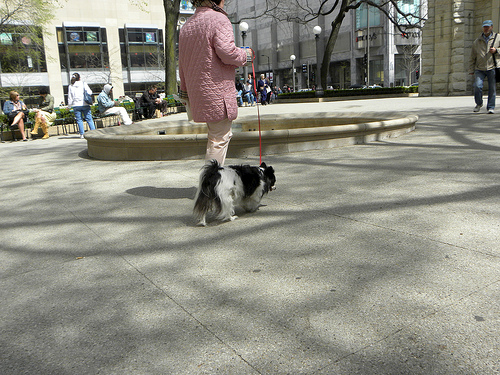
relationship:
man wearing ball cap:
[468, 20, 498, 115] [481, 17, 493, 27]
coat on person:
[175, 0, 250, 122] [178, 0, 254, 166]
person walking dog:
[178, 0, 254, 166] [196, 159, 274, 230]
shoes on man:
[467, 93, 498, 121] [469, 17, 485, 112]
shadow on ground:
[325, 106, 498, 189] [0, 95, 499, 374]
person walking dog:
[178, 0, 254, 166] [182, 154, 302, 239]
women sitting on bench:
[2, 83, 60, 142] [2, 110, 52, 142]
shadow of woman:
[127, 184, 196, 199] [177, 2, 252, 169]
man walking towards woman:
[468, 20, 500, 115] [173, 1, 255, 202]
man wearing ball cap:
[468, 20, 498, 115] [482, 19, 493, 27]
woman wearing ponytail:
[62, 67, 103, 140] [63, 61, 85, 95]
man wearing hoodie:
[468, 20, 500, 115] [94, 80, 119, 113]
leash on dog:
[251, 46, 266, 167] [188, 155, 281, 225]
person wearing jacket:
[173, 0, 243, 197] [168, 10, 258, 123]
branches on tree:
[271, 2, 334, 23] [285, 2, 424, 102]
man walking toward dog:
[468, 20, 500, 115] [188, 155, 281, 225]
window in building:
[53, 23, 115, 82] [3, 2, 171, 137]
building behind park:
[3, 2, 171, 137] [5, 76, 498, 373]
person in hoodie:
[94, 82, 131, 126] [97, 83, 122, 109]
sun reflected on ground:
[2, 92, 484, 371] [2, 93, 484, 371]